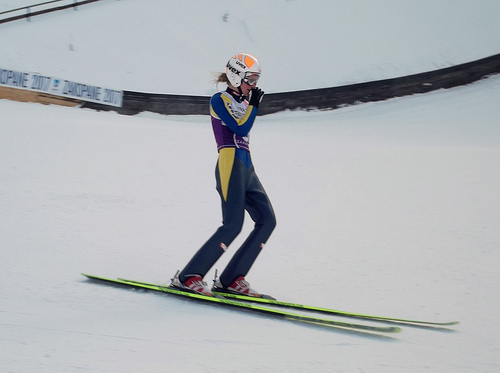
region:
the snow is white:
[362, 270, 379, 300]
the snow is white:
[349, 277, 364, 289]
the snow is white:
[372, 290, 379, 313]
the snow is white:
[373, 280, 385, 307]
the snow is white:
[358, 284, 368, 297]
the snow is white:
[354, 291, 363, 301]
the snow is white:
[379, 273, 387, 300]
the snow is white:
[380, 277, 392, 299]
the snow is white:
[374, 280, 381, 295]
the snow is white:
[127, 327, 144, 342]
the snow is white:
[152, 333, 176, 359]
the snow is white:
[202, 339, 217, 361]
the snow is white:
[191, 345, 215, 366]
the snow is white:
[184, 357, 191, 362]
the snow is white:
[209, 345, 222, 362]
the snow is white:
[199, 330, 219, 359]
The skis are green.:
[57, 226, 468, 355]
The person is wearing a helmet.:
[215, 37, 290, 77]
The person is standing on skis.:
[161, 29, 349, 309]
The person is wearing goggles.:
[225, 70, 277, 95]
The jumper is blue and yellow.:
[192, 106, 275, 271]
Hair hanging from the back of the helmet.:
[208, 57, 236, 97]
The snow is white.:
[80, 136, 197, 223]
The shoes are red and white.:
[176, 266, 283, 312]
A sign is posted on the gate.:
[11, 61, 138, 115]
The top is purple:
[210, 115, 264, 152]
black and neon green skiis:
[87, 255, 458, 341]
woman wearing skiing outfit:
[174, 26, 308, 293]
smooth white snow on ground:
[59, 125, 151, 226]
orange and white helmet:
[219, 52, 268, 92]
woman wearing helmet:
[210, 53, 265, 102]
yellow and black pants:
[179, 161, 278, 301]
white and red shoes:
[160, 266, 290, 318]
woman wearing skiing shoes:
[197, 60, 277, 255]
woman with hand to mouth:
[217, 59, 262, 103]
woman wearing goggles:
[222, 54, 261, 100]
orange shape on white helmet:
[244, 53, 254, 68]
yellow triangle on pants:
[218, 148, 238, 198]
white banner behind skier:
[0, 70, 122, 112]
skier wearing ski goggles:
[243, 74, 258, 87]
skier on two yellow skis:
[82, 266, 458, 340]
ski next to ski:
[83, 270, 402, 353]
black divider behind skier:
[2, 53, 499, 112]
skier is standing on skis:
[164, 51, 278, 303]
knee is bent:
[251, 210, 281, 235]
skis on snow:
[83, 270, 460, 337]